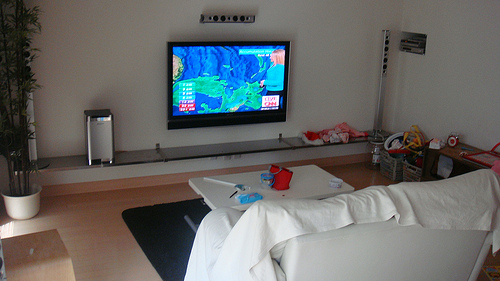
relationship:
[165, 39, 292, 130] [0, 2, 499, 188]
tv on wall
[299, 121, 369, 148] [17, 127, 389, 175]
clothes on shelf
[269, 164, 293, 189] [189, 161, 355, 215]
bag on table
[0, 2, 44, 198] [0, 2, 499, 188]
plant near wall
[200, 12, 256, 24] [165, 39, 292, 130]
speaker above tv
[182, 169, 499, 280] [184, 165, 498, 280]
cover on couch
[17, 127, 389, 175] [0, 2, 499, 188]
shelf on wall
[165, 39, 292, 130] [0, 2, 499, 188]
tv mounted on wall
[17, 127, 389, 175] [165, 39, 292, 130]
shelf below tv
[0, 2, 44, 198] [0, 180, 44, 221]
plant in pot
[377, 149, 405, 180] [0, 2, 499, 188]
carton against wall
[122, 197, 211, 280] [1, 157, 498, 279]
rug on floor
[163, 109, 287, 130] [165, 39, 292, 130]
edge of tv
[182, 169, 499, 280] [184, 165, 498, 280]
cover draped over couch